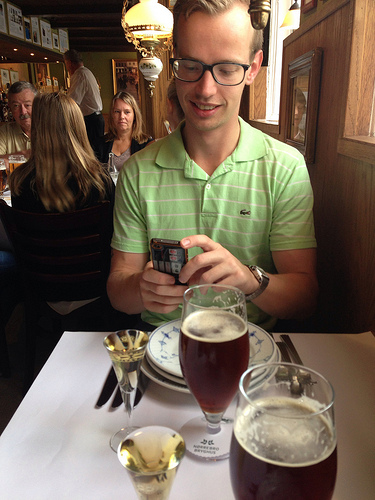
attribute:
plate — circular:
[146, 311, 277, 386]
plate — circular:
[137, 319, 283, 396]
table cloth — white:
[339, 335, 369, 495]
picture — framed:
[280, 48, 322, 161]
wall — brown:
[140, 1, 373, 331]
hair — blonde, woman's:
[34, 97, 89, 190]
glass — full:
[172, 276, 258, 463]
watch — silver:
[246, 263, 270, 301]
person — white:
[91, 11, 355, 349]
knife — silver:
[95, 360, 122, 409]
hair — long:
[6, 89, 113, 214]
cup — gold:
[100, 330, 145, 413]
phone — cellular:
[141, 235, 192, 294]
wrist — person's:
[244, 254, 278, 311]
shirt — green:
[114, 126, 318, 253]